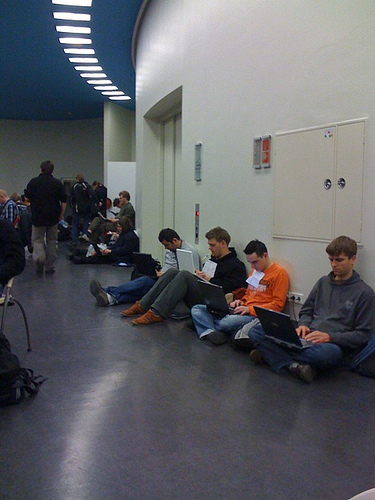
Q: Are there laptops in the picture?
A: Yes, there is a laptop.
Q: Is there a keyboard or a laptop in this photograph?
A: Yes, there is a laptop.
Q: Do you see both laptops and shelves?
A: No, there is a laptop but no shelves.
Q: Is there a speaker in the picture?
A: No, there are no speakers.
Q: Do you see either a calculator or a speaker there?
A: No, there are no speakers or calculators.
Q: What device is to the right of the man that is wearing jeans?
A: The device is a laptop.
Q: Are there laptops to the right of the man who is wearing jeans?
A: Yes, there is a laptop to the right of the man.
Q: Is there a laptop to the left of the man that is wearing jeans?
A: No, the laptop is to the right of the man.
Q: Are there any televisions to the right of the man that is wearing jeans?
A: No, there is a laptop to the right of the man.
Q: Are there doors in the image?
A: Yes, there are doors.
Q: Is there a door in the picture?
A: Yes, there are doors.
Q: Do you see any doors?
A: Yes, there are doors.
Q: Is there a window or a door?
A: Yes, there are doors.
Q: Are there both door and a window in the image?
A: No, there are doors but no windows.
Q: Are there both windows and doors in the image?
A: No, there are doors but no windows.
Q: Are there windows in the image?
A: No, there are no windows.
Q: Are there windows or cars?
A: No, there are no windows or cars.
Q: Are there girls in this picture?
A: No, there are no girls.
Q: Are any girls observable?
A: No, there are no girls.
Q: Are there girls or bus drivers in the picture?
A: No, there are no girls or bus drivers.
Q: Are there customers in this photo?
A: No, there are no customers.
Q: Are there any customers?
A: No, there are no customers.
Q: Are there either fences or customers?
A: No, there are no customers or fences.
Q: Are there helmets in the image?
A: No, there are no helmets.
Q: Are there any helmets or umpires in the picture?
A: No, there are no helmets or umpires.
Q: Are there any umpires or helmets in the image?
A: No, there are no helmets or umpires.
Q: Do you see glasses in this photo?
A: No, there are no glasses.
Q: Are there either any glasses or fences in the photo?
A: No, there are no glasses or fences.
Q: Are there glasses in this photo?
A: No, there are no glasses.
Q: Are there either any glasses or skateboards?
A: No, there are no glasses or skateboards.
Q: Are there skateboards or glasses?
A: No, there are no glasses or skateboards.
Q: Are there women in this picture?
A: No, there are no women.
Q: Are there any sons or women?
A: No, there are no women or sons.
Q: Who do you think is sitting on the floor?
A: The man is sitting on the floor.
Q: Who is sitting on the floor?
A: The man is sitting on the floor.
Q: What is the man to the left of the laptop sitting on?
A: The man is sitting on the floor.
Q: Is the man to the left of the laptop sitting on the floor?
A: Yes, the man is sitting on the floor.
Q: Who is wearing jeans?
A: The man is wearing jeans.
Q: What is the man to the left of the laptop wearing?
A: The man is wearing jeans.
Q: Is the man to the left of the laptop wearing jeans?
A: Yes, the man is wearing jeans.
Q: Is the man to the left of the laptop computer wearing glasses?
A: No, the man is wearing jeans.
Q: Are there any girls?
A: No, there are no girls.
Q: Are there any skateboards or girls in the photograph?
A: No, there are no girls or skateboards.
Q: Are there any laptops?
A: Yes, there is a laptop.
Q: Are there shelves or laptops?
A: Yes, there is a laptop.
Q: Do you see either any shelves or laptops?
A: Yes, there is a laptop.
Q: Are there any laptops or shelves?
A: Yes, there is a laptop.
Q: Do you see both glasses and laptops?
A: No, there is a laptop but no glasses.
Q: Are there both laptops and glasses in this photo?
A: No, there is a laptop but no glasses.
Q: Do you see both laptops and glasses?
A: No, there is a laptop but no glasses.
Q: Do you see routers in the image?
A: No, there are no routers.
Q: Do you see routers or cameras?
A: No, there are no routers or cameras.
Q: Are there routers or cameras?
A: No, there are no routers or cameras.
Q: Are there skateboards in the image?
A: No, there are no skateboards.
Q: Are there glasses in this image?
A: No, there are no glasses.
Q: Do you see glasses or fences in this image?
A: No, there are no glasses or fences.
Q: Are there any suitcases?
A: No, there are no suitcases.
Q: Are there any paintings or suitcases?
A: No, there are no suitcases or paintings.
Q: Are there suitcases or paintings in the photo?
A: No, there are no suitcases or paintings.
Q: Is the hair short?
A: Yes, the hair is short.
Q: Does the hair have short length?
A: Yes, the hair is short.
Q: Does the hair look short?
A: Yes, the hair is short.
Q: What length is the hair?
A: The hair is short.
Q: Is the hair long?
A: No, the hair is short.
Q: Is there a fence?
A: No, there are no fences.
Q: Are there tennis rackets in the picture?
A: No, there are no tennis rackets.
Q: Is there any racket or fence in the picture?
A: No, there are no rackets or fences.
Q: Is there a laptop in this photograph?
A: Yes, there is a laptop.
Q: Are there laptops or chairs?
A: Yes, there is a laptop.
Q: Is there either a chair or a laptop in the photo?
A: Yes, there is a laptop.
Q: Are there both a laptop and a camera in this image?
A: No, there is a laptop but no cameras.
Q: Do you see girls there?
A: No, there are no girls.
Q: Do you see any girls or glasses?
A: No, there are no girls or glasses.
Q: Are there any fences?
A: No, there are no fences.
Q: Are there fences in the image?
A: No, there are no fences.